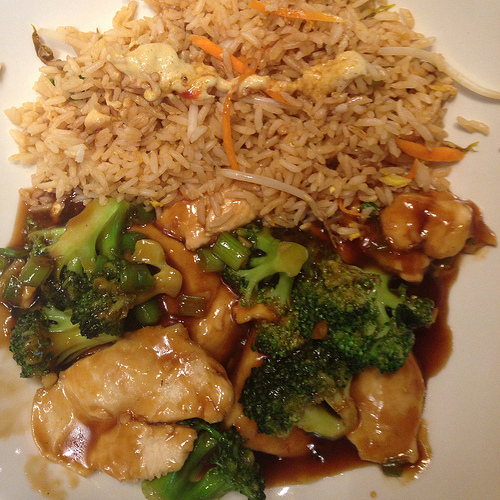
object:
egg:
[106, 42, 370, 104]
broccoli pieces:
[7, 189, 163, 377]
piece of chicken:
[24, 318, 238, 494]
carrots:
[189, 30, 293, 172]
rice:
[3, 0, 486, 229]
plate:
[0, 1, 500, 499]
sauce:
[391, 276, 456, 375]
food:
[0, 1, 500, 498]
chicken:
[28, 320, 238, 484]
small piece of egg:
[101, 41, 372, 106]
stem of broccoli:
[24, 196, 136, 303]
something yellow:
[378, 172, 413, 189]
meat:
[357, 187, 498, 284]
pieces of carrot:
[390, 129, 475, 172]